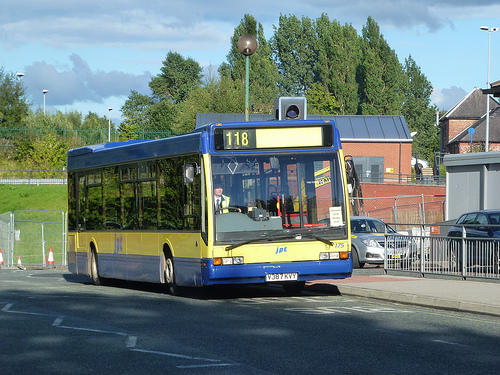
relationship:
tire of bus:
[160, 254, 180, 297] [64, 117, 354, 294]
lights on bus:
[213, 256, 244, 266] [64, 117, 354, 294]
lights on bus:
[318, 250, 350, 261] [64, 117, 354, 294]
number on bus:
[222, 125, 252, 148] [27, 54, 394, 370]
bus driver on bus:
[208, 180, 237, 217] [196, 102, 354, 286]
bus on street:
[64, 117, 354, 294] [0, 262, 500, 375]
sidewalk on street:
[341, 273, 498, 317] [3, 262, 494, 367]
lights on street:
[13, 70, 114, 113] [3, 262, 494, 367]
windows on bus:
[77, 160, 191, 234] [64, 117, 354, 294]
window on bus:
[211, 154, 338, 231] [64, 117, 354, 294]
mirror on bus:
[182, 161, 199, 180] [57, 108, 359, 297]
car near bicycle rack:
[345, 212, 427, 274] [375, 218, 498, 288]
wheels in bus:
[56, 231, 200, 309] [64, 117, 354, 294]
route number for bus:
[212, 122, 329, 150] [56, 112, 387, 295]